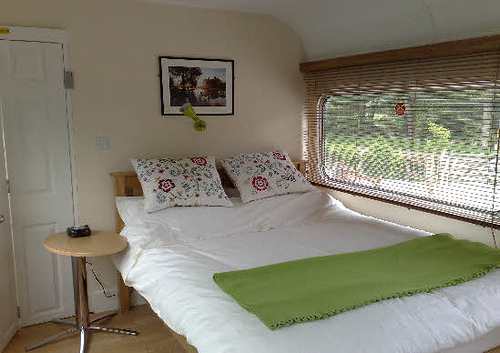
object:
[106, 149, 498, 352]
bed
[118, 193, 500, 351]
comforter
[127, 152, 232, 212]
pillow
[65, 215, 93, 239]
clock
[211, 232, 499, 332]
blanket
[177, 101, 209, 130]
stuffed toy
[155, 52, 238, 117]
picture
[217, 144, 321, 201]
pillow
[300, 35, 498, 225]
blinds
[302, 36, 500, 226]
window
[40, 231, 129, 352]
table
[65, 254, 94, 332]
leg